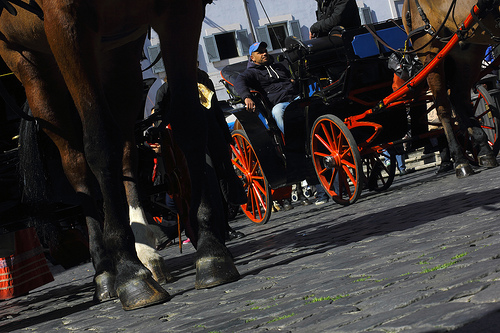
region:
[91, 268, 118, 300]
Back left horses hoof on the closest left horse.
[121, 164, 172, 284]
A white horse leg and hoof between a set of black legs.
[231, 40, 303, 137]
A man in a carriage with a blue hat on and black sweatshirt.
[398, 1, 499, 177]
A brown side of a horse that is pulling a carriage with a man wearing a blue hat.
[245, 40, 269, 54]
Blue ball cap on a man in a carriage.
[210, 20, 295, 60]
Two black windows on each side of a man in a blue hats head.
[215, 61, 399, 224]
An orange and black carriage a horse is pulling.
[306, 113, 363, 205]
The closest orange and black front wheel.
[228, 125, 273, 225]
A back large orange and black wheel on a carriage.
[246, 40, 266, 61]
Blue hat on a mans head.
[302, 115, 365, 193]
Orange wheel on a cartage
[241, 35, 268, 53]
man wearing a baseball cap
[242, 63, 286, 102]
man wearing a blue sweatshirt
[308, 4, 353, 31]
man wearing a black jacket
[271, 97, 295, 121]
man wearing blue jeans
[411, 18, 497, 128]
horse pulling a carriage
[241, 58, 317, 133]
man sitting a carriage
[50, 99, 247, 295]
horse on a brick pavement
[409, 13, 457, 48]
straps on a horse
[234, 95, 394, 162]
orange and black carriage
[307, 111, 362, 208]
red wooden wagon wheel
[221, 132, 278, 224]
red wooden wagon wheel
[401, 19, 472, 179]
brown leg of horse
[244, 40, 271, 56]
person wearing blue baseball hat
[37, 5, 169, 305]
front leg on brown horse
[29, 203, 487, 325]
cobble stone pathway with horse and carriage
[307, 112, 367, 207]
wheel with black tire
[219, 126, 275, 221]
black tire on red wooden wheel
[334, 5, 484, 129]
red hook up for horse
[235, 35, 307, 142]
person riding in carriage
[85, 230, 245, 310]
black horse hoofs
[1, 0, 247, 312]
brown horse with black hooves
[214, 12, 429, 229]
blue wahon with red and black wheels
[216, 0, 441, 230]
brown horse pulling blue carriage with red and black wheels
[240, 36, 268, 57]
blue baseball cap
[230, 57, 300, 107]
black sweatshirt with white drawstrings and hood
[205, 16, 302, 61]
two windows on side of grey building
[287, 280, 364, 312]
grass growing through grey brick pavement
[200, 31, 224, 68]
shutters on side of window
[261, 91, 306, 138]
pair of blue jeans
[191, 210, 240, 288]
a large horse's hoof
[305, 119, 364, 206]
a red wooden wheel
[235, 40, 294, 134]
a man in a hoodie and cap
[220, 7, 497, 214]
a horse drawn carriage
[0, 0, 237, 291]
the underside of a brown horse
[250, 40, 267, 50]
a blue baseball cap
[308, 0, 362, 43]
a man in a black coat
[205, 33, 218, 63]
blue shutters to a window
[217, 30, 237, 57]
a window to a house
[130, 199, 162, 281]
a white hoof of a horse